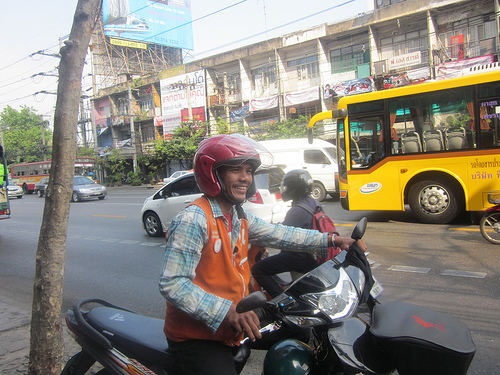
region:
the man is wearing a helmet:
[192, 133, 253, 198]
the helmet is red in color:
[193, 136, 270, 201]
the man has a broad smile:
[229, 179, 249, 192]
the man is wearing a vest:
[171, 200, 254, 345]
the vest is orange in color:
[166, 194, 259, 327]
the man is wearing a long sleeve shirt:
[166, 196, 330, 333]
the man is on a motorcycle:
[76, 140, 473, 371]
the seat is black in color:
[88, 297, 183, 369]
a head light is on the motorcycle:
[308, 268, 359, 323]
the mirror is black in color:
[238, 288, 280, 322]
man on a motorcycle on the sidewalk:
[66, 134, 474, 373]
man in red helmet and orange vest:
[159, 133, 366, 373]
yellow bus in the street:
[318, 66, 498, 223]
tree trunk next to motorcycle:
[31, 0, 101, 373]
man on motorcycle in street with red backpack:
[257, 169, 341, 293]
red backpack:
[312, 208, 338, 260]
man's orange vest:
[172, 203, 254, 342]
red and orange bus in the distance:
[11, 158, 96, 190]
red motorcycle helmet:
[196, 135, 257, 200]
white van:
[255, 137, 352, 200]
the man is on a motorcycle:
[48, 132, 471, 373]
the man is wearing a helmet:
[188, 121, 269, 210]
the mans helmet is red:
[192, 123, 263, 210]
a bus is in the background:
[306, 59, 499, 221]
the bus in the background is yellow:
[300, 72, 495, 239]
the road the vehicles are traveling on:
[21, 156, 495, 334]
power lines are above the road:
[5, 0, 335, 107]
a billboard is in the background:
[104, 3, 198, 51]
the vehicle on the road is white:
[133, 153, 296, 243]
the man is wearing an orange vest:
[161, 202, 266, 347]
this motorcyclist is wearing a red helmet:
[190, 130, 273, 205]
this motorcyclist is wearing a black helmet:
[277, 165, 315, 202]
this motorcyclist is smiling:
[189, 129, 268, 207]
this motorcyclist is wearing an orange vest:
[156, 193, 261, 350]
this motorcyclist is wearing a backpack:
[304, 204, 343, 267]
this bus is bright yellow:
[305, 67, 497, 216]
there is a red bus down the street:
[8, 157, 98, 194]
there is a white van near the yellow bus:
[245, 133, 350, 201]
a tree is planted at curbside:
[25, 48, 95, 374]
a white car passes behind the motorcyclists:
[137, 158, 297, 241]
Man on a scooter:
[153, 125, 338, 348]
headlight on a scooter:
[305, 270, 356, 320]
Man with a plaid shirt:
[162, 213, 239, 325]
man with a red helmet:
[189, 126, 256, 195]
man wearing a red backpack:
[314, 211, 351, 256]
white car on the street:
[124, 154, 209, 231]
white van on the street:
[281, 125, 338, 191]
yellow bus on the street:
[331, 100, 452, 224]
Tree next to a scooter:
[39, 154, 111, 374]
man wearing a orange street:
[181, 213, 248, 315]